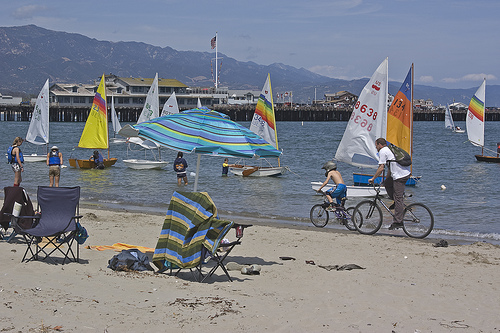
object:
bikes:
[309, 188, 363, 231]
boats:
[310, 56, 388, 198]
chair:
[3, 185, 84, 266]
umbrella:
[127, 108, 286, 194]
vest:
[49, 151, 61, 166]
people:
[7, 137, 24, 188]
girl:
[173, 151, 188, 186]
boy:
[316, 160, 347, 225]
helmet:
[321, 161, 337, 177]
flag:
[207, 30, 224, 86]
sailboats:
[4, 79, 50, 163]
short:
[324, 183, 347, 207]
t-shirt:
[377, 146, 412, 180]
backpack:
[387, 143, 412, 166]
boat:
[69, 73, 118, 170]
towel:
[151, 191, 235, 273]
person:
[222, 158, 236, 177]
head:
[375, 137, 386, 152]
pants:
[384, 172, 412, 223]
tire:
[351, 200, 383, 235]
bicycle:
[351, 180, 434, 239]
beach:
[0, 199, 499, 333]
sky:
[0, 2, 498, 90]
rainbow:
[467, 93, 485, 122]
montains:
[0, 23, 496, 108]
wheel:
[400, 202, 435, 240]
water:
[0, 119, 498, 242]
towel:
[106, 248, 155, 272]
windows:
[201, 98, 206, 106]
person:
[368, 137, 422, 226]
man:
[368, 137, 411, 230]